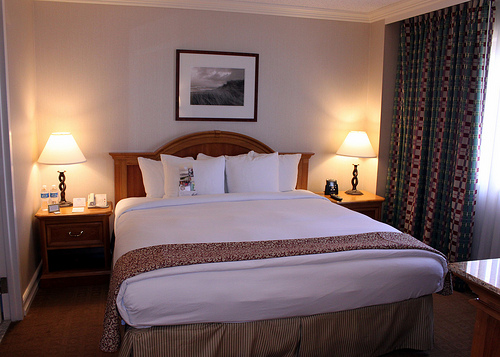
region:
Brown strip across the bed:
[102, 229, 454, 350]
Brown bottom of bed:
[121, 290, 435, 355]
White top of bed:
[112, 192, 443, 328]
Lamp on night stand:
[331, 125, 377, 195]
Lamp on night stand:
[36, 122, 86, 205]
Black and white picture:
[173, 42, 262, 125]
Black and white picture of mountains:
[186, 64, 245, 109]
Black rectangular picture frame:
[173, 45, 259, 127]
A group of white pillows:
[132, 146, 302, 197]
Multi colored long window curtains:
[379, 0, 499, 261]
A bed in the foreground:
[92, 116, 467, 353]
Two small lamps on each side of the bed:
[30, 110, 385, 235]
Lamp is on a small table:
[31, 105, 121, 300]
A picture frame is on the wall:
[160, 40, 270, 135]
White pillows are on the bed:
[125, 135, 310, 192]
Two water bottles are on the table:
[35, 171, 65, 211]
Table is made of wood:
[26, 186, 120, 301]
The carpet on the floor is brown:
[0, 266, 498, 355]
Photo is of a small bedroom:
[4, 2, 498, 351]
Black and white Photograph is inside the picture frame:
[183, 60, 250, 112]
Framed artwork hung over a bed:
[173, 45, 260, 123]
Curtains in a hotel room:
[386, 4, 479, 259]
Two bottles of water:
[39, 181, 59, 211]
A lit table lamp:
[336, 128, 378, 198]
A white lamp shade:
[333, 128, 378, 159]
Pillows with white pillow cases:
[131, 151, 305, 195]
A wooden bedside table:
[34, 199, 113, 295]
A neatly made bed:
[103, 130, 451, 355]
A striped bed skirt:
[115, 304, 441, 355]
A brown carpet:
[33, 282, 98, 355]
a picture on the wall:
[155, 43, 292, 125]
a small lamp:
[37, 133, 89, 213]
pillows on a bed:
[134, 141, 314, 199]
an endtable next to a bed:
[29, 176, 127, 282]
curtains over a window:
[367, 16, 490, 242]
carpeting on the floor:
[40, 281, 99, 346]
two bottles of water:
[34, 178, 65, 208]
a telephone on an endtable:
[82, 188, 115, 213]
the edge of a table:
[447, 243, 499, 302]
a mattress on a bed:
[112, 190, 449, 317]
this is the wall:
[92, 33, 140, 81]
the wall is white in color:
[297, 56, 344, 98]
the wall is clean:
[290, 40, 330, 84]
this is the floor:
[45, 295, 85, 327]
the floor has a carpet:
[36, 288, 89, 334]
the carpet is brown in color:
[51, 313, 80, 335]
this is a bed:
[113, 126, 443, 352]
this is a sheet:
[185, 217, 222, 228]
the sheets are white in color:
[239, 205, 303, 232]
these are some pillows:
[132, 144, 308, 199]